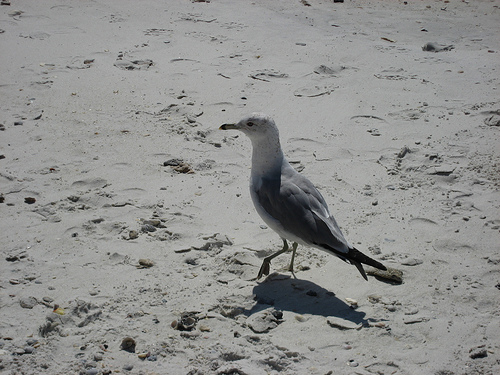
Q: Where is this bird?
A: On a beach.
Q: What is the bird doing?
A: Walking on sand.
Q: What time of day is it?
A: Daytime.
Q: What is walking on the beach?
A: A bird.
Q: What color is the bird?
A: White and grey.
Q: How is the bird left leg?
A: About to take a step.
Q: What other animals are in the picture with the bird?
A: Nothing.